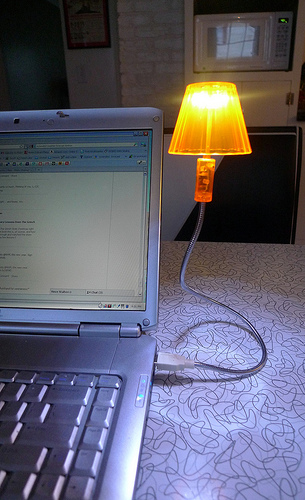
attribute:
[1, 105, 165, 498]
laptop — on, indoors, silver, plastic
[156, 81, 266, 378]
lamp — orange, on, yellow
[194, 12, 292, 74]
microwave — white, shiny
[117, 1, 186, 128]
bricks — white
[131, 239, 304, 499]
surface — white, patterned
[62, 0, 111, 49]
poster — hanging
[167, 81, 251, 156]
shade — orange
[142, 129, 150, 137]
x — red, white